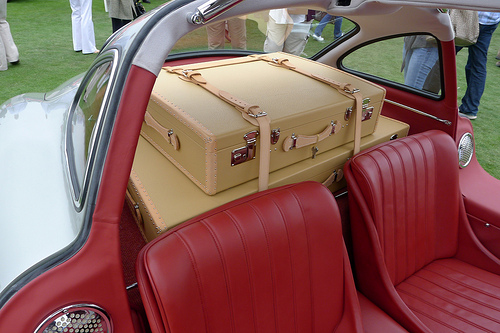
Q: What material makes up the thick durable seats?
A: Leather.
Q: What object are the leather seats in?
A: Car.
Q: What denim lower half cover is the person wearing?
A: Jeans.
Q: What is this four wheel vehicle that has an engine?
A: Car.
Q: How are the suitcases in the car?
A: Stacked up.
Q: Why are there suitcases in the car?
A: To travel.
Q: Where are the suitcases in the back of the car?
A: Trunk.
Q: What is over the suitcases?
A: A set of straps.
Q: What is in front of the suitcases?
A: A couple of red seats.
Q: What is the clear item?
A: A side window.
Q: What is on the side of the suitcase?
A: Tan handles.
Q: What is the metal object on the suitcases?
A: Silver locks.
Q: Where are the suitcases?
A: In the back of a car.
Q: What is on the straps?
A: Silver buckles.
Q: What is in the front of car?
A: A red seat.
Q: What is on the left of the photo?
A: A red car seat.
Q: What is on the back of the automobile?
A: A large rear window.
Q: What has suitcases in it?
A: A red and white vehicle.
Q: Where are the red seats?
A: In a vehicle.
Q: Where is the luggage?
A: In the backseat of a vehicle.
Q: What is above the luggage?
A: The vehicle windows.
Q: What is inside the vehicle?
A: Red seats.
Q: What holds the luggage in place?
A: A strap holds the luggage in the vehicle.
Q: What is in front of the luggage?
A: Red seats.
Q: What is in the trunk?
A: Matching tan suitcases.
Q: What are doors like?
A: Raised.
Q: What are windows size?
A: Small.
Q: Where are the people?
A: Behind car.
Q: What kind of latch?
A: Metal.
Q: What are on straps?
A: Clips.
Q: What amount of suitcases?
A: Two.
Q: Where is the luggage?
A: Back seat.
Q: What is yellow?
A: Luggage.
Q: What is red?
A: The seats.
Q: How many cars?
A: 1.